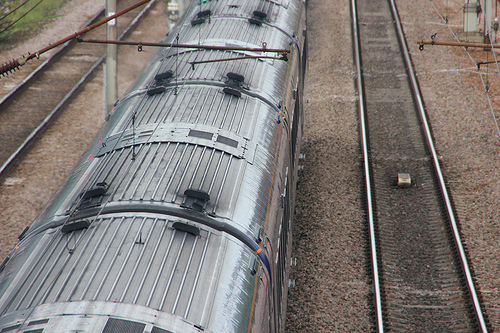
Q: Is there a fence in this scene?
A: No, there are no fences.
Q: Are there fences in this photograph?
A: No, there are no fences.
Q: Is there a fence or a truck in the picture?
A: No, there are no fences or trucks.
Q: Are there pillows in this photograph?
A: No, there are no pillows.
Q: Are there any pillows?
A: No, there are no pillows.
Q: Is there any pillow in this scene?
A: No, there are no pillows.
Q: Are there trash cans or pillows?
A: No, there are no pillows or trash cans.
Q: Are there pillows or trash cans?
A: No, there are no pillows or trash cans.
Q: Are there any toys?
A: No, there are no toys.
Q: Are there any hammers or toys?
A: No, there are no toys or hammers.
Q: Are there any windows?
A: Yes, there is a window.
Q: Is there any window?
A: Yes, there is a window.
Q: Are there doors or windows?
A: Yes, there is a window.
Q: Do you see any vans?
A: No, there are no vans.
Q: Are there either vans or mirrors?
A: No, there are no vans or mirrors.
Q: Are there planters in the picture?
A: No, there are no planters.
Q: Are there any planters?
A: No, there are no planters.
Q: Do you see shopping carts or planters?
A: No, there are no planters or shopping carts.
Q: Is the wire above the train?
A: Yes, the wire is above the train.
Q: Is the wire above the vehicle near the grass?
A: Yes, the wire is above the train.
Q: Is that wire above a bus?
A: No, the wire is above the train.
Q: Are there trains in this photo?
A: Yes, there is a train.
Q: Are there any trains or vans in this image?
A: Yes, there is a train.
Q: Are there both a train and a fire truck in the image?
A: No, there is a train but no fire trucks.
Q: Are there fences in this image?
A: No, there are no fences.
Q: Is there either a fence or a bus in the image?
A: No, there are no fences or buses.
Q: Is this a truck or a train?
A: This is a train.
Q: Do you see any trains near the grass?
A: Yes, there is a train near the grass.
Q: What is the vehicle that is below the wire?
A: The vehicle is a train.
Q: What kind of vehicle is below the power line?
A: The vehicle is a train.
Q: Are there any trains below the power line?
A: Yes, there is a train below the power line.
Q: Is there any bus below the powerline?
A: No, there is a train below the powerline.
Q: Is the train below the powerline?
A: Yes, the train is below the powerline.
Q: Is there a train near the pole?
A: Yes, there is a train near the pole.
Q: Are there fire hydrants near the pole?
A: No, there is a train near the pole.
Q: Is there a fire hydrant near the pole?
A: No, there is a train near the pole.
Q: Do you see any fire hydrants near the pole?
A: No, there is a train near the pole.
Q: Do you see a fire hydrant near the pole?
A: No, there is a train near the pole.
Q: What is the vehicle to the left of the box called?
A: The vehicle is a train.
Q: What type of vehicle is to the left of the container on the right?
A: The vehicle is a train.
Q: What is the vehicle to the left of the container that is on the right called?
A: The vehicle is a train.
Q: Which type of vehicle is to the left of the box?
A: The vehicle is a train.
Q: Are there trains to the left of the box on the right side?
A: Yes, there is a train to the left of the box.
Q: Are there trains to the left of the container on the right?
A: Yes, there is a train to the left of the box.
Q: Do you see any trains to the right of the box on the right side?
A: No, the train is to the left of the box.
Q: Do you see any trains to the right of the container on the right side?
A: No, the train is to the left of the box.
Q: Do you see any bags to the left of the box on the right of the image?
A: No, there is a train to the left of the box.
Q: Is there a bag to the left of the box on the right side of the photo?
A: No, there is a train to the left of the box.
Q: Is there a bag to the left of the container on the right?
A: No, there is a train to the left of the box.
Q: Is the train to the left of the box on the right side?
A: Yes, the train is to the left of the box.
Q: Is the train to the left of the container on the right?
A: Yes, the train is to the left of the box.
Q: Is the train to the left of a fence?
A: No, the train is to the left of the box.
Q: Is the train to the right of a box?
A: No, the train is to the left of a box.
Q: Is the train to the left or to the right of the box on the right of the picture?
A: The train is to the left of the box.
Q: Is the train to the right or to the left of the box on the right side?
A: The train is to the left of the box.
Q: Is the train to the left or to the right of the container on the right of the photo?
A: The train is to the left of the box.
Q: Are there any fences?
A: No, there are no fences.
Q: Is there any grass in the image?
A: Yes, there is grass.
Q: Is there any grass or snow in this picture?
A: Yes, there is grass.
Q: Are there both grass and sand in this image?
A: No, there is grass but no sand.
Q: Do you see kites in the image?
A: No, there are no kites.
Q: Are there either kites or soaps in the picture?
A: No, there are no kites or soaps.